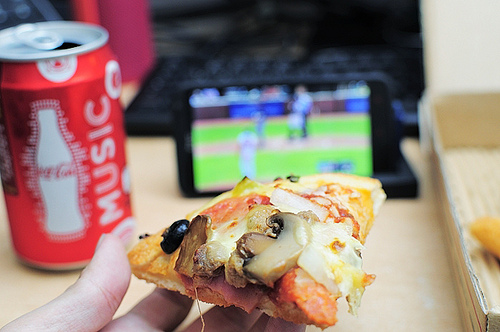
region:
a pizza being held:
[161, 139, 428, 325]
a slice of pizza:
[160, 158, 424, 323]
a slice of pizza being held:
[167, 182, 382, 330]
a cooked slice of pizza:
[165, 169, 385, 329]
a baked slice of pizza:
[135, 138, 407, 325]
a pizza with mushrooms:
[189, 179, 377, 326]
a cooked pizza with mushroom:
[179, 175, 393, 323]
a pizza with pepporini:
[186, 144, 326, 329]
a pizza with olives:
[168, 161, 381, 310]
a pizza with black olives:
[144, 135, 465, 329]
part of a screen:
[358, 135, 368, 160]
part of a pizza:
[319, 245, 336, 255]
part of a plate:
[98, 281, 106, 289]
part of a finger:
[170, 268, 172, 293]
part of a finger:
[456, 158, 470, 190]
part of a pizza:
[342, 195, 354, 212]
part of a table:
[404, 168, 412, 211]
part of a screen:
[346, 100, 363, 120]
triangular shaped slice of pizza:
[123, 173, 385, 322]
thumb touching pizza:
[3, 228, 131, 330]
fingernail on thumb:
[93, 231, 105, 248]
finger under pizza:
[110, 284, 202, 330]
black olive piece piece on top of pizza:
[160, 220, 182, 242]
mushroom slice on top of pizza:
[234, 210, 308, 282]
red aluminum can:
[0, 19, 144, 272]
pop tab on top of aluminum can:
[14, 21, 60, 49]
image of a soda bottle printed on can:
[35, 106, 85, 236]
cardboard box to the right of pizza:
[423, 81, 498, 330]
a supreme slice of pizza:
[119, 168, 394, 329]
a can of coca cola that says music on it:
[1, 13, 146, 281]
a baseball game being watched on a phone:
[177, 76, 407, 190]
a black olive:
[161, 216, 191, 253]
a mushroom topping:
[246, 205, 314, 284]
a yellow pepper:
[231, 170, 268, 203]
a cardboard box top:
[423, 83, 498, 330]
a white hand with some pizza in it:
[9, 200, 337, 330]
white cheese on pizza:
[128, 173, 392, 300]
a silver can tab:
[15, 21, 67, 52]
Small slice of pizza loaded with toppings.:
[125, 169, 389, 329]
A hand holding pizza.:
[0, 168, 390, 330]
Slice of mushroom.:
[236, 208, 313, 285]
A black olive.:
[162, 217, 192, 253]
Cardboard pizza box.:
[422, 89, 498, 330]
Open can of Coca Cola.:
[0, 19, 140, 276]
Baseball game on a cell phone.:
[174, 72, 411, 197]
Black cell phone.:
[174, 74, 405, 194]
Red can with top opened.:
[2, 19, 140, 273]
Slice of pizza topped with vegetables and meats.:
[125, 167, 389, 330]